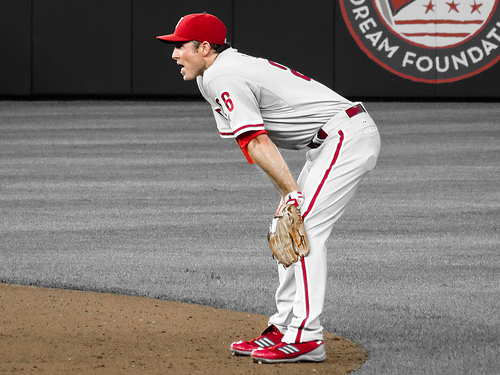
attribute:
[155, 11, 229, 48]
cap — red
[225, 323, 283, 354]
shoe — red, white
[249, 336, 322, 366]
shoe — red, white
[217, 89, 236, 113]
number — red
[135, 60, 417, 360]
player — wearing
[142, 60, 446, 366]
player — wearing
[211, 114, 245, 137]
hat — red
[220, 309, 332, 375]
shoes — grey, red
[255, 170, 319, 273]
glove — red, white